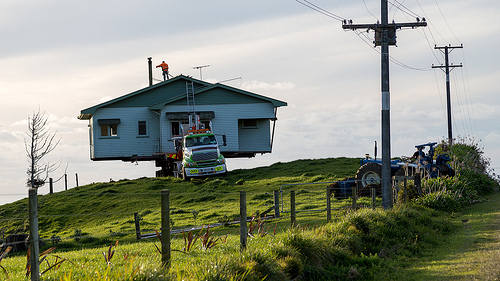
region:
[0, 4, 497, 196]
cloud cover in sky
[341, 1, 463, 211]
two telephone poles on grass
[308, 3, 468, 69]
wires above telephone poles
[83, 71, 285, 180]
house on top of truck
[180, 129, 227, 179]
front of tractor trailer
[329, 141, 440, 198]
tractor on grassy hill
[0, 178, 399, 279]
row of poles in grass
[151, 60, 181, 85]
person standing on roof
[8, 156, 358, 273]
green grass on hill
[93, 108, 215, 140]
awnings on top of windows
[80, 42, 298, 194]
Truck with a house on it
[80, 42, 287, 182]
House on a truck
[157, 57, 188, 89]
Man on the roof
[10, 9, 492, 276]
Photo taken during the day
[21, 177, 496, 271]
The field grass is green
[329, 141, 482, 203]
Blue tractor in the field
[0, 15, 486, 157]
Clouds in the sky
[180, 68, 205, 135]
Ladder to the roof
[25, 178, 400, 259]
Wooden fence posts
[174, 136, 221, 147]
Windshield on the truck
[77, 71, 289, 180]
a truck moving a large house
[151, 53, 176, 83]
a man in orange on the roof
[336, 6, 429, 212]
a white and grey utility pole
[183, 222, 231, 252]
red and gold grass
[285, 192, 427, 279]
tall grassy hills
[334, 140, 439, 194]
blue and white tractor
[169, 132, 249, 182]
white truck with green lights and stickers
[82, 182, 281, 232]
rolling green hills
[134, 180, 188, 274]
black and grey post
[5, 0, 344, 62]
grey cloudy sky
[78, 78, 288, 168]
A house on a wrecker.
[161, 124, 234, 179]
A truck bed under the house.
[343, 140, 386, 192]
A tractor in the field.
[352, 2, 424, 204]
Pole with wire on it.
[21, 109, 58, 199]
A bare tree in the yard.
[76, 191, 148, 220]
Patches on the grass.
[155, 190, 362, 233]
A gate surrounding the property.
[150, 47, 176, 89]
A man on top of the house.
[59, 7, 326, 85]
The sky is blue.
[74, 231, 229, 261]
Weeds in the grass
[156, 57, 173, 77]
The man on the roof of the house.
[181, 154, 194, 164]
The left headlight on the truck.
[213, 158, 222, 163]
The right headlight on the truck.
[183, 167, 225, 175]
The front fender of the truck.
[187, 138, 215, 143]
The front window of the truck.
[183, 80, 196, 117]
The ladder leaning against the house.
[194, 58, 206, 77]
The antennae on the roof.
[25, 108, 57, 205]
The tree on the left.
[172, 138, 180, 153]
The left side view mirror on the truck.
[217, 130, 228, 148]
The right side view mirror on the truck.